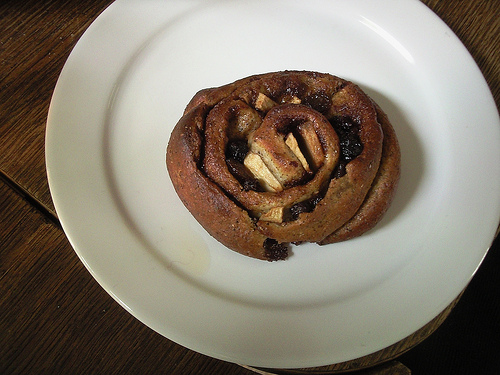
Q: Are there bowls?
A: No, there are no bowls.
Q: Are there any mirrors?
A: No, there are no mirrors.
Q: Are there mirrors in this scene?
A: No, there are no mirrors.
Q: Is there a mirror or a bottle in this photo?
A: No, there are no mirrors or bottles.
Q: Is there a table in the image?
A: Yes, there is a table.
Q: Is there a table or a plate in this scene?
A: Yes, there is a table.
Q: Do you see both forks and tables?
A: No, there is a table but no forks.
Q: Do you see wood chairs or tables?
A: Yes, there is a wood table.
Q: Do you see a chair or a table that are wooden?
A: Yes, the table is wooden.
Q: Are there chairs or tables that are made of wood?
A: Yes, the table is made of wood.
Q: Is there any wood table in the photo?
A: Yes, there is a wood table.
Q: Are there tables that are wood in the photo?
A: Yes, there is a wood table.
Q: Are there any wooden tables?
A: Yes, there is a wood table.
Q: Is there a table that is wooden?
A: Yes, there is a table that is wooden.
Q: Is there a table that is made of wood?
A: Yes, there is a table that is made of wood.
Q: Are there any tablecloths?
A: No, there are no tablecloths.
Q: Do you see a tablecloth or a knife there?
A: No, there are no tablecloths or knives.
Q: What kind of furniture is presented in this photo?
A: The furniture is a table.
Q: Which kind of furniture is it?
A: The piece of furniture is a table.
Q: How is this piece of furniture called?
A: This is a table.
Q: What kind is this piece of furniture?
A: This is a table.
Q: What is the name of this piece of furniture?
A: This is a table.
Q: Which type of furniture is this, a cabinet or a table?
A: This is a table.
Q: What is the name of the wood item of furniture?
A: The piece of furniture is a table.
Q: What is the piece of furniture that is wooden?
A: The piece of furniture is a table.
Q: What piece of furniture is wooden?
A: The piece of furniture is a table.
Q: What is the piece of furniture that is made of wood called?
A: The piece of furniture is a table.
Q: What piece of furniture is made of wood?
A: The piece of furniture is a table.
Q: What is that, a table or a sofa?
A: That is a table.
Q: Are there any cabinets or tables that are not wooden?
A: No, there is a table but it is wooden.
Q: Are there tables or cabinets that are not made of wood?
A: No, there is a table but it is made of wood.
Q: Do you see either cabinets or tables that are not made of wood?
A: No, there is a table but it is made of wood.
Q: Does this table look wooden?
A: Yes, the table is wooden.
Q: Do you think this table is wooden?
A: Yes, the table is wooden.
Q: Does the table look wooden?
A: Yes, the table is wooden.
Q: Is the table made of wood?
A: Yes, the table is made of wood.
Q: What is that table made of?
A: The table is made of wood.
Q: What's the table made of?
A: The table is made of wood.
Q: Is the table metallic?
A: No, the table is wooden.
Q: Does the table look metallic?
A: No, the table is wooden.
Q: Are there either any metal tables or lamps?
A: No, there is a table but it is wooden.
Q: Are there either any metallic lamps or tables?
A: No, there is a table but it is wooden.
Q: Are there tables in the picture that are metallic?
A: No, there is a table but it is wooden.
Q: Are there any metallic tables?
A: No, there is a table but it is wooden.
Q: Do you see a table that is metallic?
A: No, there is a table but it is wooden.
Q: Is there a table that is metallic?
A: No, there is a table but it is wooden.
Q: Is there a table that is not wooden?
A: No, there is a table but it is wooden.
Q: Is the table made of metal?
A: No, the table is made of wood.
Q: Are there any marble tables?
A: No, there is a table but it is made of wood.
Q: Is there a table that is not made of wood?
A: No, there is a table but it is made of wood.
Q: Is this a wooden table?
A: Yes, this is a wooden table.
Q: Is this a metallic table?
A: No, this is a wooden table.